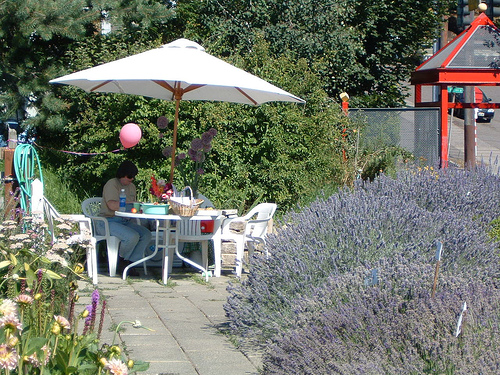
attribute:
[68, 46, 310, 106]
umbrella — white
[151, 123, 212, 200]
pole — brown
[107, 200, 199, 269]
table — round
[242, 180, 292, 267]
chair — white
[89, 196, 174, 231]
shirt — tan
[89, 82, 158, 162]
balloon — pink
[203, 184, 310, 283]
chair — white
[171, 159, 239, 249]
basket — brown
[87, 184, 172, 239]
table — white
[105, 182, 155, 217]
bottle — plastic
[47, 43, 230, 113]
umbrella — white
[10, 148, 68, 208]
hose — green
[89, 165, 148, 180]
hair — brown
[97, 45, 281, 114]
umbrella — white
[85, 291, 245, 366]
patio — grey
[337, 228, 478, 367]
bushes — lavender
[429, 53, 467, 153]
structure — red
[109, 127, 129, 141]
balloon — pink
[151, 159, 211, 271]
basket — brown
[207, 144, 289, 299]
chair — white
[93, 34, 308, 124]
umbrella — white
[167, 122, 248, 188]
balloons — purple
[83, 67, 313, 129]
umbrella — white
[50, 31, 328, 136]
umbrella — white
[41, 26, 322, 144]
umbrella — white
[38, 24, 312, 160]
umbrella — white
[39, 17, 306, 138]
umbrella — large open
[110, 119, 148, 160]
balloon — pink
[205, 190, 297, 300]
chair — white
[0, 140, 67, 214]
hose — green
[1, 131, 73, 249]
hose — green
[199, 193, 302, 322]
patio chair — white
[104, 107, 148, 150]
balloon — pink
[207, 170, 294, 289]
plastic chair — white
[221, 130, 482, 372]
bush — green and purple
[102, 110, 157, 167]
balloon — pink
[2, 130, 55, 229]
garden hose — green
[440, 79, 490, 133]
car — small black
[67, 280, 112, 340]
flower — tall skinny purple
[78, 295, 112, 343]
flower — tall skinny purple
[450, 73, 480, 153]
glass — red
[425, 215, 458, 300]
paper sign — small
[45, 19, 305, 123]
umbrella — large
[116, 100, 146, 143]
balloon — pink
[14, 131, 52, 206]
water hose — green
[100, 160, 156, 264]
woman — sitting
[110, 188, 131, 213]
bottle — water 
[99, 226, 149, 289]
legs — womans 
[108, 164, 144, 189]
head — womans 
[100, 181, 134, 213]
arm — womans 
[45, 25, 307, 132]
umbrella — white  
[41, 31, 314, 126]
umbrella — white  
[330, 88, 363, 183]
stop — red bus 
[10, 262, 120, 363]
shrubs — purple 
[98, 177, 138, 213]
shirt — tan 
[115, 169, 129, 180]
sunglasses — black  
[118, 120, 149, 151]
balloon — pink 